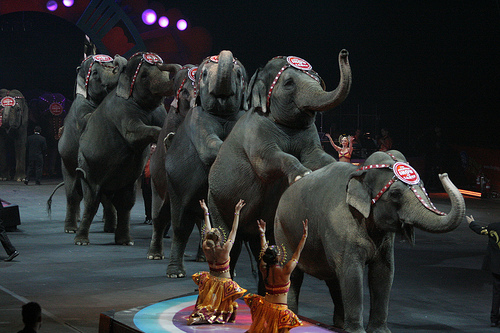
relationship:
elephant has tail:
[46, 53, 128, 235] [45, 181, 65, 219]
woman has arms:
[196, 198, 248, 323] [228, 198, 244, 253]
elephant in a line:
[46, 53, 128, 235] [43, 49, 462, 331]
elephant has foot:
[46, 53, 128, 235] [65, 198, 81, 236]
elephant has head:
[46, 53, 128, 235] [74, 53, 130, 102]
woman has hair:
[196, 198, 248, 323] [203, 226, 223, 250]